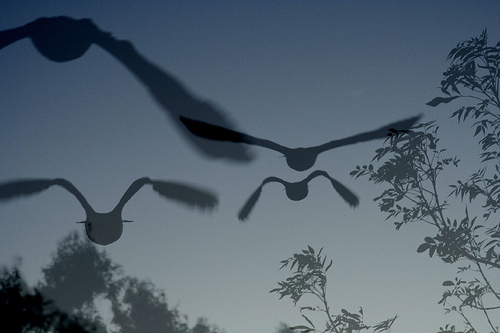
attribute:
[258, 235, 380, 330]
trees — grey, dark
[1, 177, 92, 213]
wing — blurred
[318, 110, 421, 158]
wing — outstretched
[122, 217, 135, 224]
line — black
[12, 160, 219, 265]
wings — fuzzy 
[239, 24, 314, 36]
sky — blue , darker 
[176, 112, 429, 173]
drone — grey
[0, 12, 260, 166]
shadow — bird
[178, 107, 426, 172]
shadow — bird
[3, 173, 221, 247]
shadow — bird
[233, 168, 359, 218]
shadow — bird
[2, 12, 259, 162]
bird — flying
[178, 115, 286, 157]
wing — outstretched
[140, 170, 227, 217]
wing — fluffy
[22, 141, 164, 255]
something — large , grey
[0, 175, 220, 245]
bird — flying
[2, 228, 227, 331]
tree line — black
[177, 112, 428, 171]
bird — flying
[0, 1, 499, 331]
sky — blue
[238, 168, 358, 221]
bird — flying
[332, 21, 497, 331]
tree — tall